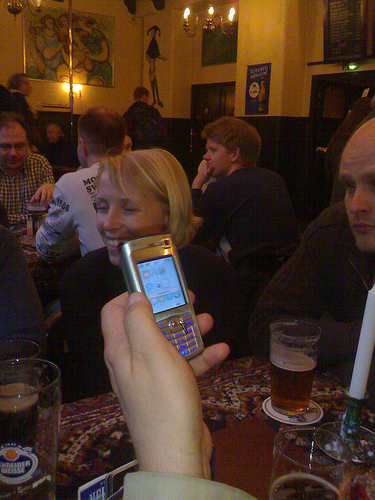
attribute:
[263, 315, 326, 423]
glass — half full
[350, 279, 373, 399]
candle — white, long, unlit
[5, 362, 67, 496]
pint glass — empty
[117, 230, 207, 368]
cell phone — lit up, small, silver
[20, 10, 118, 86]
picture — large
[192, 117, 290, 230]
man — young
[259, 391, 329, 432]
coaster — paper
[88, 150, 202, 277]
woman — blonde, smiling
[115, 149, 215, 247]
woman's hair — short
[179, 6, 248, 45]
lights — hanging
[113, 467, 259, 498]
sleeve — tan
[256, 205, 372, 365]
jacket — brown